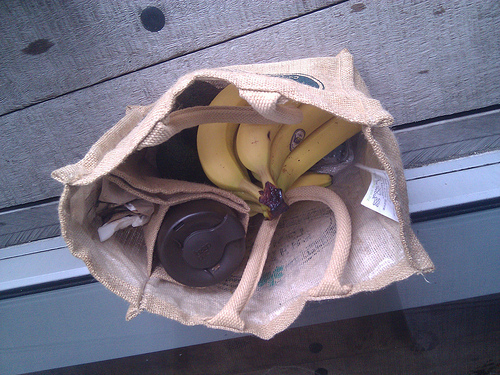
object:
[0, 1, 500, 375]
board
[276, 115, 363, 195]
banana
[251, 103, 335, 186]
banana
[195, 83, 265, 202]
banana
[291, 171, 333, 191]
banana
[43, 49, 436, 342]
bag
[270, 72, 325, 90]
ink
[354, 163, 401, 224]
tag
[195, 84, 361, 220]
fruit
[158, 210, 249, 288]
black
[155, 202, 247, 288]
lid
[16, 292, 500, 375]
floor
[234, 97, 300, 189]
banana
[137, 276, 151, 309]
stiches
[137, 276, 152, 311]
seam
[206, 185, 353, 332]
handle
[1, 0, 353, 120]
crack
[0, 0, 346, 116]
wood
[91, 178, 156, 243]
bag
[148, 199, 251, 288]
mug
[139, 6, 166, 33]
marks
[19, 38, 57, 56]
marks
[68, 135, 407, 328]
back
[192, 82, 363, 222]
bunch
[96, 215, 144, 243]
material